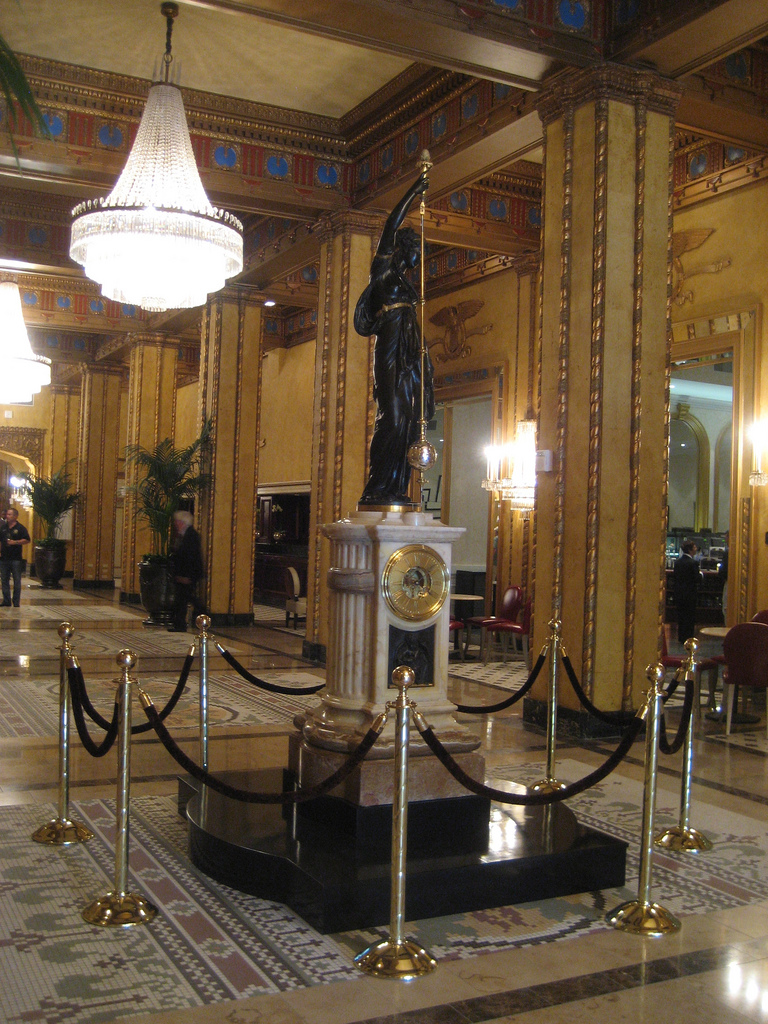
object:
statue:
[293, 149, 481, 759]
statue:
[325, 142, 470, 742]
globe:
[408, 440, 437, 472]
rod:
[408, 149, 437, 471]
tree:
[17, 457, 83, 546]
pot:
[35, 546, 67, 590]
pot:
[138, 562, 176, 631]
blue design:
[268, 156, 289, 178]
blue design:
[318, 164, 338, 186]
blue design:
[214, 144, 237, 168]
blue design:
[99, 126, 123, 147]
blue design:
[40, 114, 63, 136]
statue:
[354, 149, 436, 512]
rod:
[406, 139, 443, 479]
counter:
[665, 569, 729, 646]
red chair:
[484, 595, 531, 666]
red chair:
[464, 585, 524, 660]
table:
[451, 594, 484, 660]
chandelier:
[69, 0, 244, 312]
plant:
[118, 418, 217, 561]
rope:
[74, 635, 197, 734]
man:
[674, 539, 704, 643]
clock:
[382, 543, 451, 620]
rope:
[412, 694, 651, 806]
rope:
[559, 644, 687, 725]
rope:
[454, 636, 553, 715]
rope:
[211, 635, 326, 695]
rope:
[66, 655, 121, 757]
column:
[306, 506, 468, 743]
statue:
[350, 175, 447, 507]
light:
[482, 419, 537, 512]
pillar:
[524, 60, 687, 728]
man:
[168, 509, 203, 631]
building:
[0, 0, 768, 1024]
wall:
[256, 340, 316, 484]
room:
[0, 3, 768, 1024]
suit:
[170, 527, 203, 583]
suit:
[675, 554, 702, 609]